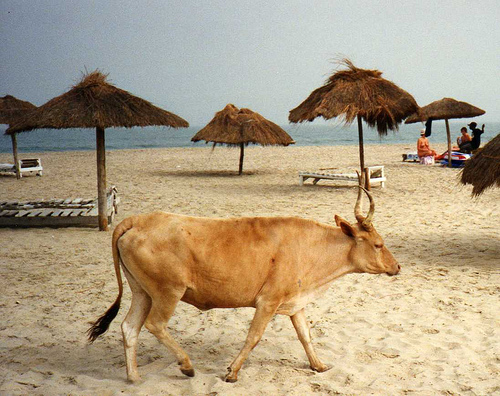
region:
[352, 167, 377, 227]
pointy horns of a cow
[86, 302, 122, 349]
bushy black tail of cow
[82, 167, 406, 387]
a brown cow with pointy horns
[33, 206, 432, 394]
a cow walking on sand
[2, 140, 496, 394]
yellow sand on the beach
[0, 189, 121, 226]
white lounge chairs on the beach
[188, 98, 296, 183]
brown umbrella on the beach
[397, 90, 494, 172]
people sitting under umbrella on the beach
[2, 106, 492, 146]
blue clear body of water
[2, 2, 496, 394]
a sandy beach with umbrellas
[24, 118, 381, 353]
cow on a beach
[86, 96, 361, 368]
cow on a beach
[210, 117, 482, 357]
cow on a beach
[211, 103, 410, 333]
cow on a beach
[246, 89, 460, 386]
cow on a beach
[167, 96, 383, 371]
cow on a beach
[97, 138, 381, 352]
cow on a beach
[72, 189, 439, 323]
cow on a beach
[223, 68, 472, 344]
cow on a beach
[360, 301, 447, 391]
sand is light brown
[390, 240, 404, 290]
cow has brown nose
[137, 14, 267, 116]
white and grey sky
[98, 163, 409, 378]
a cow with twisted upright horns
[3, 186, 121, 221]
lounge chairs on the sand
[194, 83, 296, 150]
thatched umbrellas on the beach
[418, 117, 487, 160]
people picnoc on the beach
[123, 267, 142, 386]
cow is wnite at the inner leg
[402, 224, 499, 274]
shadow of the thatch unbrella on the sand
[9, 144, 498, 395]
sand on the wide beach has many foot prints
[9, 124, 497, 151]
the water appears grey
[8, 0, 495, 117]
the sky above the water looks hazy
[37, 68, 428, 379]
a cow walking on the beach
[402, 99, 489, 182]
three people at the beach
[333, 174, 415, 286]
the head of a cow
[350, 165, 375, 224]
the horns of a cow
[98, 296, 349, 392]
the legs of a cow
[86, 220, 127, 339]
the tail of a cow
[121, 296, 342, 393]
the legs of a cow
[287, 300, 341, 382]
the leg of a cow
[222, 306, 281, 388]
the leg of a cow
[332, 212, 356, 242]
the ear of a cow